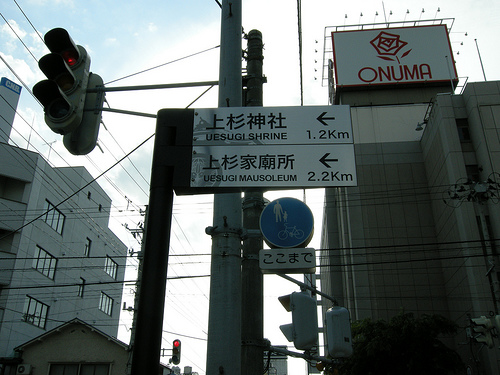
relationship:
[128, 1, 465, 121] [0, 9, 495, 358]
clouds in sky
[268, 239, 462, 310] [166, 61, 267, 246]
wires on pole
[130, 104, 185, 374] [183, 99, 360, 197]
pole with signs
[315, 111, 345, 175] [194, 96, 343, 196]
arrows on signs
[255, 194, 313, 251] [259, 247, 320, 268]
sign over rectangle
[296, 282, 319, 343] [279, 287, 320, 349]
side of traffic light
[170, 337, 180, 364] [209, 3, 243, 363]
light on post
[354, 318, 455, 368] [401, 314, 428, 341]
tree with leaves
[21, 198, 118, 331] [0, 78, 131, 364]
windows on building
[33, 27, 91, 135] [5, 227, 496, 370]
stop light hanging above street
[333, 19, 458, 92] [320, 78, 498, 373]
sign on building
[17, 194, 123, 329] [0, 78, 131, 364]
windows on building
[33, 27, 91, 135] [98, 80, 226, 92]
stop light on pole